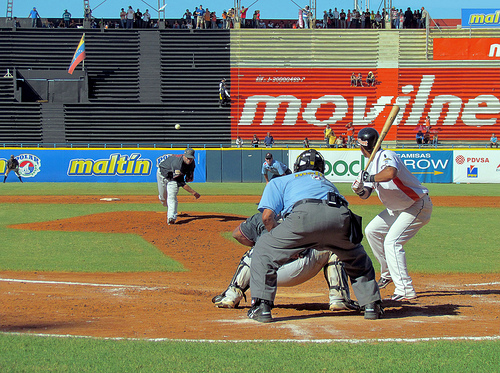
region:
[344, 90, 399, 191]
Man holding a wooden bat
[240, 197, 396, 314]
empire wearing gray pants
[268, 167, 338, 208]
man wearing a blue shirt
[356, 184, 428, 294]
player wearing white pants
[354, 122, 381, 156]
man wearing blue helmet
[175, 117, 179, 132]
baseball being pitched to batter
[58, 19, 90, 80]
flag on a pole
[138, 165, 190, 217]
person wearing gray pants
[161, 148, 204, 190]
man wearing a black jersey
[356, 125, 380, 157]
man wearing a blue helmet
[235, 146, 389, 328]
The umpire is kneeling.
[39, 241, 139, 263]
This grass is green.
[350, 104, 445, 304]
The batter is a lefty.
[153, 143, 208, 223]
The pitcher is a righty.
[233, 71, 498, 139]
Movilne sponsors this team.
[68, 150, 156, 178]
Maltin sponsors this team.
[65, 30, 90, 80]
The flag is yellow, blue, and red.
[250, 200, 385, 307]
The umps pants are grey.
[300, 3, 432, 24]
There are people in the stands.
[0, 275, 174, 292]
The chalk is smudged.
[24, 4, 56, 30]
People standing up in the stands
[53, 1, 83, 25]
People standing up in the stands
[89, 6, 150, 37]
People standing up in the stands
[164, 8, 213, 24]
People standing up in the stands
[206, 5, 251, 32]
People standing up in the stands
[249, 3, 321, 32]
People standing up in the stands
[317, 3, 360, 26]
People standing up in the stands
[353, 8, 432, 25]
People standing up in the stands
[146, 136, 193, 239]
Person in a baseball field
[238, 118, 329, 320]
Person in a baseball field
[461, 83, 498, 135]
The letter is white.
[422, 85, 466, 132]
The letter is white.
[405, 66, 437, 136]
The letter is white.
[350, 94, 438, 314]
The man is wearing a baseball uniform.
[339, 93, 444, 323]
The man is holding a baseball bat.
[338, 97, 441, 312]
The man is wearing a baseball helmet.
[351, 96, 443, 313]
The man's knees are slightly bent.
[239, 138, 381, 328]
The man is crouching.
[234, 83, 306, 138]
The letter is white.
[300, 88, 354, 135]
The letter is white.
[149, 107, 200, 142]
A baseball in mid air.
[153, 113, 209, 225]
Pitcher throwing the ball to the batter.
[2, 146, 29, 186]
An outfielder waiting to catch the ball.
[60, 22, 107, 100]
A flag blowing in the distance.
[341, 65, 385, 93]
Three fans sitting on the bleachers.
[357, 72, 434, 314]
Player getting ready to hit the ball.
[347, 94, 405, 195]
Player holding a baseball bat.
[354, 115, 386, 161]
Player wearing a helmet for safety.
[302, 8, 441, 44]
Fans watching the game.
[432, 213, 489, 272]
Bright green grass on the field.